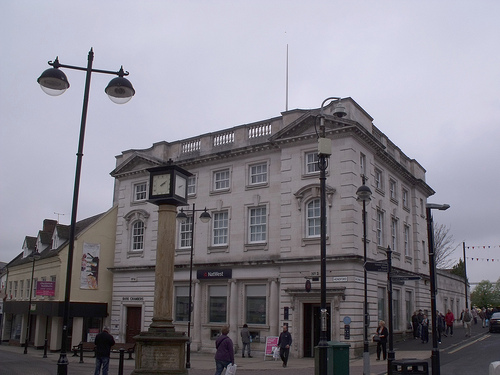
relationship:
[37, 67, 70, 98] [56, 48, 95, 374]
light on post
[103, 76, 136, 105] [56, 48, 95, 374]
light on post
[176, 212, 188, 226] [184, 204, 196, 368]
light on post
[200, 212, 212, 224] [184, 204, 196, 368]
light on post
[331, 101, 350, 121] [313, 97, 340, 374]
light on post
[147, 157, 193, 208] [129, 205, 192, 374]
clock on tower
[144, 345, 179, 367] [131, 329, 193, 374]
lettering on base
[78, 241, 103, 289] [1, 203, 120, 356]
banner on building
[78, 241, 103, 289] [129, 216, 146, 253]
banner near window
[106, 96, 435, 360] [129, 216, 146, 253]
building has window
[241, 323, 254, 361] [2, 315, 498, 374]
person on sidewalk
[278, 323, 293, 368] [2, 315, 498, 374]
person on sidewalk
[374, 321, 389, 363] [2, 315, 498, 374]
person on sidewalk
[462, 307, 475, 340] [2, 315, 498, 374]
person on sidewalk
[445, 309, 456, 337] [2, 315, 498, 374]
person on sidewalk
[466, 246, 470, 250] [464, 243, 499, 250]
flag on line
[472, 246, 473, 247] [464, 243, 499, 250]
flag on line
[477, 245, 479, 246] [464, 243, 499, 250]
flag on line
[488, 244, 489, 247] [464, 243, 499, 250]
flag on line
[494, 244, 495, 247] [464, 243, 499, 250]
flag on line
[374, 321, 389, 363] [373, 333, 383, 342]
person carrying bag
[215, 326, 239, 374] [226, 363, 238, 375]
person carrying bag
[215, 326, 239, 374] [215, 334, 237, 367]
person wearing jacket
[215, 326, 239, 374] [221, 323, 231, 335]
person has hair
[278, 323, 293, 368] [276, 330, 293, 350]
person wearing jacket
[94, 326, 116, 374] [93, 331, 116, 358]
person wearing jacket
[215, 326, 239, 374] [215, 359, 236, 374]
person wearing jeans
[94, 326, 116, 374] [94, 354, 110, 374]
person wearing jeans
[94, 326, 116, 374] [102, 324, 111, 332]
person has hair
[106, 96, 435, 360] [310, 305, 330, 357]
building has door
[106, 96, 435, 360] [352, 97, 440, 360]
building has side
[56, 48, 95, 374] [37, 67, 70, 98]
post has light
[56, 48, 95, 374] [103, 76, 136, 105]
post has light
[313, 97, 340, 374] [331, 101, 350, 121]
post has light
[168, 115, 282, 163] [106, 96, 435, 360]
railing on top of building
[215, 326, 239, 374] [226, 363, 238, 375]
person has bag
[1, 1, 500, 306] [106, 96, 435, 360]
sky above building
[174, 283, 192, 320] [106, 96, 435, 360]
window on building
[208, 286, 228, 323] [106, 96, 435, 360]
window on building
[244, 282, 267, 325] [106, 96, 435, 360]
window on building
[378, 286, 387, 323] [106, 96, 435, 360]
window on building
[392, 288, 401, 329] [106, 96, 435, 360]
window on building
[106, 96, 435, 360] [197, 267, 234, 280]
building has a logo